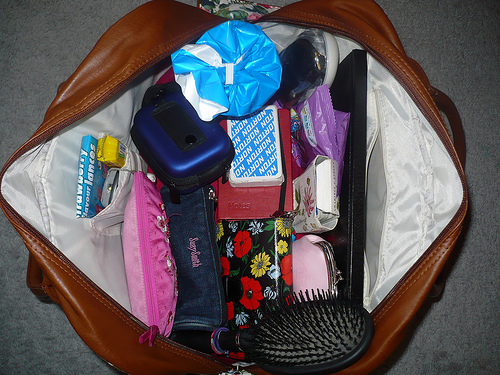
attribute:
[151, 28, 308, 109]
bag — sanitary towels, light blue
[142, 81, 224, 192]
case — blue, black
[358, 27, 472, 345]
zipper — brown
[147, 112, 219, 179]
purse — pink, small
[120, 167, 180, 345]
pouch — pink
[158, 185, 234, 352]
zipper case — tubular, long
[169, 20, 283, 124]
plastic — white-edged, blue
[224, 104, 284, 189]
cards — deck, small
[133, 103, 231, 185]
case — blue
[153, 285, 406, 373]
hairbrush — black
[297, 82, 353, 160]
product — hygiene, feminine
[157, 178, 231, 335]
case — denim, small, zippered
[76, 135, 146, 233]
interior pocket — grey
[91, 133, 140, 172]
candy — package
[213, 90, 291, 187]
cards — white, blue, playing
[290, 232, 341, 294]
pink pocketbook — little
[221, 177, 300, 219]
pink pocketbook — little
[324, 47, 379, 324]
tablet — thin, black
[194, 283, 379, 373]
hair brush — black, boar bristle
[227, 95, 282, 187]
box — blue, white, plastic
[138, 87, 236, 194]
container — metal, blue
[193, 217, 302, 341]
case — black, floral-patterned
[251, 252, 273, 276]
flower — black, yellow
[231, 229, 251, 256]
flower — red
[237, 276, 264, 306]
flower — red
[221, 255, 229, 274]
flower — red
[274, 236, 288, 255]
flower — yellow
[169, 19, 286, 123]
object — light blue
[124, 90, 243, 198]
case — plastic, black, blue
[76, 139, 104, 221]
gum — strawberry-flavored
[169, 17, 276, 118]
bag — white, blue 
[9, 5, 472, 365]
case — brown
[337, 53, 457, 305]
lining — pocketed, silky, white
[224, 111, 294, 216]
case — telephone, red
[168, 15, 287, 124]
item — packaged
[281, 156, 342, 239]
cigarette pack — white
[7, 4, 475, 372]
bag — leather, brown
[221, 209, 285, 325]
background — black